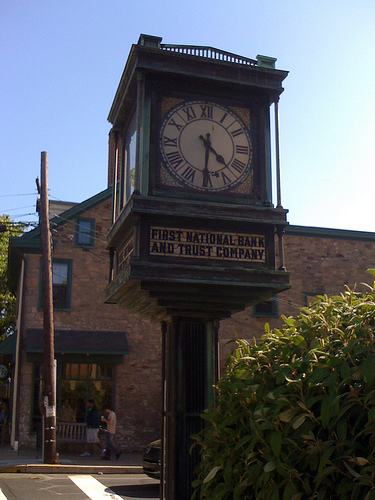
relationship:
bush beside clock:
[189, 268, 375, 500] [103, 30, 295, 499]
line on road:
[67, 474, 124, 499] [2, 469, 167, 498]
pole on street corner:
[40, 151, 57, 465] [0, 470, 165, 497]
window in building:
[72, 215, 95, 246] [1, 172, 373, 455]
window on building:
[28, 340, 118, 458] [33, 27, 373, 396]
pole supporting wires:
[18, 153, 59, 286] [1, 192, 117, 251]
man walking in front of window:
[100, 404, 122, 460] [27, 352, 113, 442]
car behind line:
[136, 430, 253, 479] [53, 460, 132, 496]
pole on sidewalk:
[40, 151, 57, 465] [75, 454, 164, 495]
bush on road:
[192, 282, 372, 493] [0, 472, 164, 500]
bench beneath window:
[56, 422, 94, 455] [22, 322, 126, 447]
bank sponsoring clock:
[227, 232, 266, 253] [160, 95, 240, 183]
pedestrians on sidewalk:
[73, 389, 126, 457] [36, 452, 140, 476]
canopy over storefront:
[0, 325, 20, 353] [2, 353, 147, 468]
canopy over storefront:
[20, 328, 135, 366] [2, 353, 147, 468]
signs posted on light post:
[148, 223, 265, 260] [133, 59, 268, 478]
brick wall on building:
[22, 195, 374, 454] [1, 172, 373, 455]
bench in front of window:
[37, 415, 113, 454] [25, 330, 127, 460]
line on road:
[67, 472, 124, 499] [0, 472, 161, 498]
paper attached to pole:
[43, 406, 54, 416] [40, 150, 61, 462]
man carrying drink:
[97, 403, 120, 444] [97, 409, 107, 422]